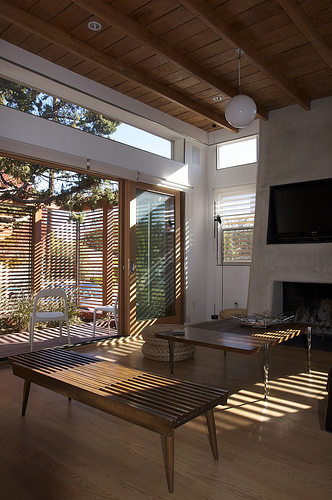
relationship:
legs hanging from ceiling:
[150, 433, 232, 482] [61, 14, 323, 131]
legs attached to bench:
[150, 433, 232, 482] [18, 349, 218, 456]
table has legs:
[153, 315, 322, 377] [170, 345, 291, 385]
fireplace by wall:
[270, 266, 330, 319] [166, 145, 332, 312]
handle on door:
[126, 255, 138, 274] [121, 189, 189, 325]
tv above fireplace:
[259, 174, 331, 254] [270, 266, 330, 319]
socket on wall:
[229, 297, 241, 318] [166, 145, 332, 312]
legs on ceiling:
[150, 433, 232, 482] [61, 14, 323, 131]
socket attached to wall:
[229, 297, 241, 318] [166, 145, 332, 312]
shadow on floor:
[174, 366, 309, 417] [60, 350, 319, 481]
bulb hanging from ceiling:
[230, 101, 244, 127] [61, 14, 323, 131]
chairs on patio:
[27, 287, 122, 353] [10, 197, 125, 354]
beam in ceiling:
[41, 32, 267, 90] [61, 14, 323, 131]